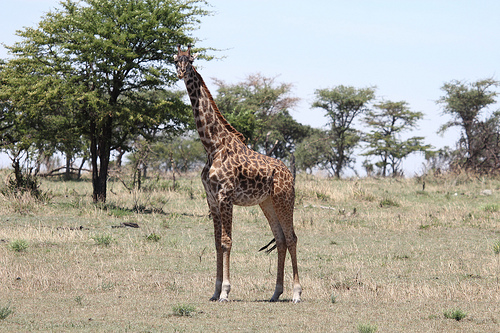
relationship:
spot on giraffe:
[218, 152, 230, 163] [168, 47, 305, 304]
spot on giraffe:
[191, 89, 199, 100] [168, 47, 305, 304]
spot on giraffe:
[209, 125, 217, 140] [168, 47, 305, 304]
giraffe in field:
[154, 41, 310, 309] [23, 123, 495, 331]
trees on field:
[18, 24, 310, 211] [24, 169, 460, 301]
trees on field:
[260, 52, 499, 192] [24, 169, 460, 301]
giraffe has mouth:
[154, 41, 310, 309] [177, 69, 189, 79]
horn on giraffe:
[185, 41, 193, 54] [168, 47, 305, 304]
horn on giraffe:
[185, 41, 192, 53] [168, 47, 305, 304]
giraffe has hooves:
[168, 47, 305, 304] [209, 286, 306, 304]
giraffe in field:
[154, 41, 310, 309] [64, 196, 422, 331]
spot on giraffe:
[190, 96, 197, 107] [168, 47, 305, 304]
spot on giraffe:
[199, 124, 220, 145] [198, 111, 215, 131]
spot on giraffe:
[205, 109, 214, 130] [168, 47, 305, 304]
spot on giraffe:
[262, 165, 282, 183] [179, 53, 315, 305]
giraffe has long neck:
[154, 41, 310, 309] [179, 76, 231, 151]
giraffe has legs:
[168, 47, 305, 304] [206, 217, 221, 300]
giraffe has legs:
[168, 47, 305, 304] [216, 204, 232, 301]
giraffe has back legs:
[154, 41, 310, 309] [280, 201, 325, 306]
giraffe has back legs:
[154, 41, 310, 309] [260, 202, 288, 293]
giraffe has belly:
[168, 47, 305, 304] [236, 172, 271, 209]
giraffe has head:
[168, 47, 305, 304] [175, 44, 191, 77]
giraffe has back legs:
[168, 47, 305, 304] [274, 196, 304, 294]